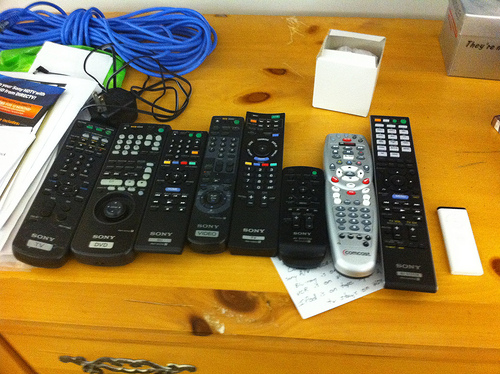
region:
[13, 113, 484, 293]
a collection of remotes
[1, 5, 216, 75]
a long blue bound wire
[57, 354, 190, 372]
metal handle on a desk drawer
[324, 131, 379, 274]
a silver comcast remote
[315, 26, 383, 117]
a small white cardboard box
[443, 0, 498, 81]
a silver carboard box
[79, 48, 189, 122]
a black charger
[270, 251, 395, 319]
a note on a white piece of paper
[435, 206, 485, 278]
a small white remote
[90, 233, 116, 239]
sony in white on a remote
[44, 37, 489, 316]
a row of remote controls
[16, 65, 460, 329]
a row of remotes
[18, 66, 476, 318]
a row of remotes on a table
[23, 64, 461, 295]
eight different remotes controls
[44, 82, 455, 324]
remotes that are different size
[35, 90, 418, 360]
different sizes remote controls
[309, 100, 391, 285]
a silver remote control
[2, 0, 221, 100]
a blue wire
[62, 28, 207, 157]
a dc power cord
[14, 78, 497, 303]
remotes on a brown table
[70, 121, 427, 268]
eight controllers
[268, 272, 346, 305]
and index card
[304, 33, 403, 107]
a white box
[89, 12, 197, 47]
a blue chord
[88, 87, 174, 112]
a black charger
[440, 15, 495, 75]
a silver box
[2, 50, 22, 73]
a green bag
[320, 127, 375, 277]
A silver controller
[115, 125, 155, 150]
buttons on the controller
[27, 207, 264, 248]
black sony controllers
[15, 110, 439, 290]
various remotes on top of a dresser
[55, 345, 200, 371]
golden handle of a drawer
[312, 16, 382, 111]
a small white box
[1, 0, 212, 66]
a bunch of blue wires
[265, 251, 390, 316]
a white note tucked under a remote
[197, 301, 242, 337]
white paint on a dresser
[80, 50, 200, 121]
a black plug and its wire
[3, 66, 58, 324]
a stack of papers on a dresser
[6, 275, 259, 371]
a wooden dresser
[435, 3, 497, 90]
a silver box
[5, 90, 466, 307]
Several remote controls are together.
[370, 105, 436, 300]
The remote control is black.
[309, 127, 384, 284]
The remote control is silver.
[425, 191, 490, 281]
The remote control is white.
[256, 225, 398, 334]
A piece of paper is under the remotes.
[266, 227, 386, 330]
The paper has writing on it.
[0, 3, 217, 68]
A blue cord is on the table.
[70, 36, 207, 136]
An adaptor is on the table.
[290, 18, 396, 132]
A box is on the table.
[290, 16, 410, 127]
The box is open.